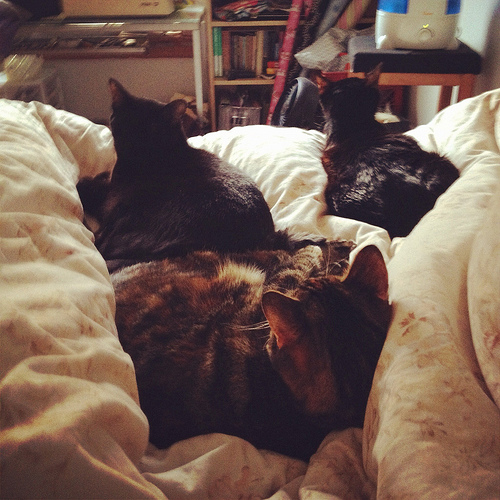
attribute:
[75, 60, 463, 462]
cats — brown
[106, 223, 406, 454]
cat — striped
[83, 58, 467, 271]
cats — black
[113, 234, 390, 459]
cat — striped, brown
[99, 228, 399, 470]
cat — brown, striped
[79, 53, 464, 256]
cats — black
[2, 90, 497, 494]
blanket — floral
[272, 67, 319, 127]
fan — black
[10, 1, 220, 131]
desk — white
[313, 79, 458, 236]
cat — black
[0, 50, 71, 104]
storage — plastic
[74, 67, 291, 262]
cat — black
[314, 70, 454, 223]
cat — black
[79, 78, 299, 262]
cat — black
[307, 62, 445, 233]
cat — black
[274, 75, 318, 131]
fan — black